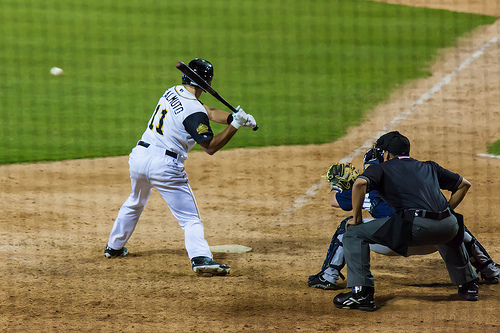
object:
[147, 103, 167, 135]
number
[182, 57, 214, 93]
helmet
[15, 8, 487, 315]
field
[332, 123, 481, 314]
empire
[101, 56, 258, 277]
athlete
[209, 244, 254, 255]
plate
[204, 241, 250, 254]
object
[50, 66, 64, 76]
ball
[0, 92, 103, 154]
grass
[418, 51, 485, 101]
line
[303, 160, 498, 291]
catcher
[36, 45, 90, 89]
baseball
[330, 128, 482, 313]
catcher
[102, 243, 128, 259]
shoe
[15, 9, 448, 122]
infield grass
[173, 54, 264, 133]
bat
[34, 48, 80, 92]
air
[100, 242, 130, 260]
foot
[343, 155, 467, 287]
dark blue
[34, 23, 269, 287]
pitch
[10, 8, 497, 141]
infield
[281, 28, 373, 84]
grass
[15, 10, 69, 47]
grass